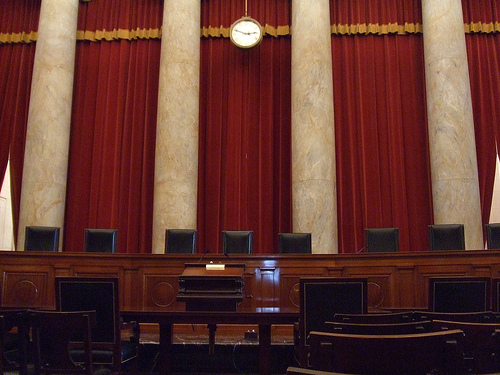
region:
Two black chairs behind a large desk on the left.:
[25, 224, 119, 254]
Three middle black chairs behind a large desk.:
[162, 228, 313, 256]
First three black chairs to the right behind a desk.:
[363, 223, 498, 251]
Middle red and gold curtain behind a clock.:
[194, 0, 295, 254]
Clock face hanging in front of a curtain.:
[227, 18, 263, 48]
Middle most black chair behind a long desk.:
[221, 229, 253, 256]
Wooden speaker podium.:
[177, 259, 247, 314]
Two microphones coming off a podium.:
[197, 247, 232, 267]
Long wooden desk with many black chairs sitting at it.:
[2, 249, 498, 337]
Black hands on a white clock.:
[232, 26, 259, 35]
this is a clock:
[225, 11, 262, 48]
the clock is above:
[227, 12, 266, 46]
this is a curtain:
[205, 87, 280, 183]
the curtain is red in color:
[210, 87, 285, 170]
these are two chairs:
[364, 222, 461, 250]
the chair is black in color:
[432, 226, 459, 248]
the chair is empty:
[282, 233, 296, 255]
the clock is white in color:
[230, 15, 263, 44]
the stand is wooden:
[190, 313, 278, 363]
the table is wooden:
[385, 250, 438, 287]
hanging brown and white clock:
[224, 0, 266, 50]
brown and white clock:
[227, 13, 265, 49]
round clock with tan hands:
[230, 12, 262, 47]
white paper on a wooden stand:
[176, 246, 252, 356]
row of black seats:
[22, 221, 497, 251]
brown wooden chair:
[20, 310, 97, 373]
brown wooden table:
[122, 310, 305, 371]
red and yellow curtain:
[328, 1, 419, 252]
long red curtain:
[328, 0, 430, 252]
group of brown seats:
[288, 314, 498, 373]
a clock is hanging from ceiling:
[212, 11, 304, 86]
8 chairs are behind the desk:
[18, 191, 498, 263]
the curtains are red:
[0, 1, 488, 256]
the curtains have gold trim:
[2, 13, 498, 58]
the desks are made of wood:
[0, 244, 494, 362]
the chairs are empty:
[2, 196, 498, 276]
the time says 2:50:
[229, 5, 299, 73]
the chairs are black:
[19, 203, 497, 259]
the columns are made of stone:
[21, 0, 498, 251]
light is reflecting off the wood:
[250, 261, 301, 324]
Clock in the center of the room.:
[216, 8, 333, 88]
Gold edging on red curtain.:
[60, 25, 159, 67]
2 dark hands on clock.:
[226, 9, 280, 94]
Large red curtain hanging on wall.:
[21, 34, 493, 193]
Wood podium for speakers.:
[176, 246, 273, 346]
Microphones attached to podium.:
[187, 242, 271, 302]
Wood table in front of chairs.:
[120, 300, 358, 362]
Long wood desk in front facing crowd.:
[48, 242, 479, 316]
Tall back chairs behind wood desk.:
[22, 204, 489, 254]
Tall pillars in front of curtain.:
[18, 79, 416, 201]